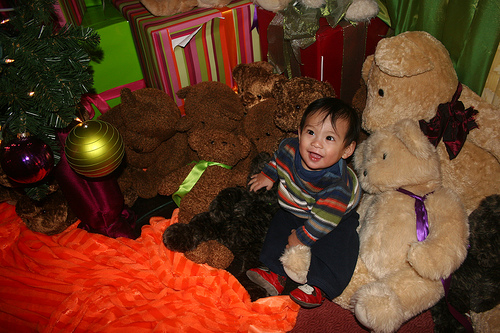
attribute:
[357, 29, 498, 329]
teddy bear — Beige, fuzzy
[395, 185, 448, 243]
ribbon — purple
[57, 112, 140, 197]
ornament — Round, green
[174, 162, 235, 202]
ribbon — green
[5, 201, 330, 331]
blanket — orange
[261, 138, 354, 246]
sweater — long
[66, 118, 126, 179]
ornament — green, large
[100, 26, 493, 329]
bears — large, brown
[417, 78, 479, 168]
bow — maroon 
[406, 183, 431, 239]
tie — purple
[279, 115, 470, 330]
teddy bear — Beige , fuzzy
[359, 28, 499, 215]
teddy bear — Light brown, fuzzy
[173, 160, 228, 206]
ribbon — green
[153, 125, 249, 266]
brown teddybear — fuzzy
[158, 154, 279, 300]
teddy bear — dark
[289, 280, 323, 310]
shoe — red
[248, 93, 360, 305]
child — young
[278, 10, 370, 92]
box — wrapped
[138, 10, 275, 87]
box — wrapped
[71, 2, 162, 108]
box — wrapped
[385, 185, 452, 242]
ribbon — Purple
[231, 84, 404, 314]
boy — small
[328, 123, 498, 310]
bear — Beige, fuzzy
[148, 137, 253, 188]
ribbon — green 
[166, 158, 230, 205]
tie — green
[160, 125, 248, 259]
teddy bear — Brown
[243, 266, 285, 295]
shoe — red